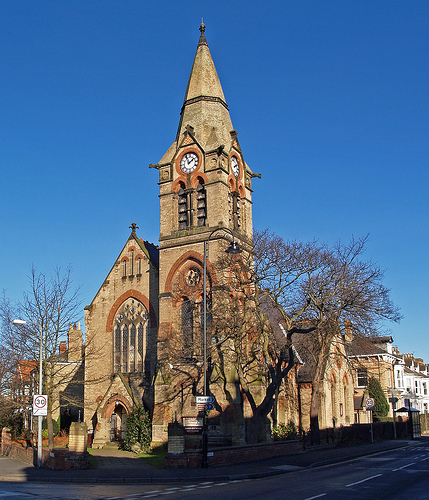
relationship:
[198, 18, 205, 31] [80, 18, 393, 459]
steeple on church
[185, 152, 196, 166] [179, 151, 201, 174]
black hands are on clock face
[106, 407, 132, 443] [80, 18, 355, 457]
doorway at church